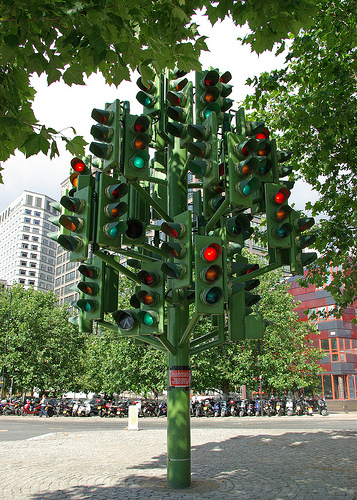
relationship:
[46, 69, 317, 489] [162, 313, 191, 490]
light connected to pole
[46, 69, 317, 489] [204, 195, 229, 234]
light connected to pole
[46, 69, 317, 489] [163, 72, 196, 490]
light connected to pole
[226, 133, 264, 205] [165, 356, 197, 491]
light connected to pole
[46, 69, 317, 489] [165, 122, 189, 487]
light on pole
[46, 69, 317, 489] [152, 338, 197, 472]
light on pole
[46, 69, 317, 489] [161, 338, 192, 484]
light on pole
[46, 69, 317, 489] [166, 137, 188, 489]
light on pole